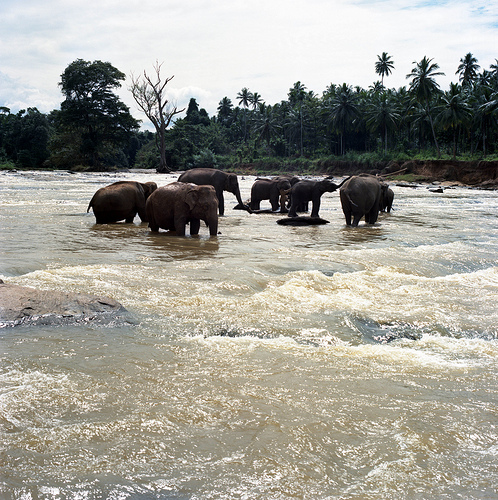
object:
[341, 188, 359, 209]
tail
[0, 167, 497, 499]
river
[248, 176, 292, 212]
animal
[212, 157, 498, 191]
riverbank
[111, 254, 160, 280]
ripples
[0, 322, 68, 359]
ripples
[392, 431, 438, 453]
ripples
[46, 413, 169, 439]
ripples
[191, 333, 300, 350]
ripples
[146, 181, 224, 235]
elephant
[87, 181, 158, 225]
elephant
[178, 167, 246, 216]
elephant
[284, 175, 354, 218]
elephant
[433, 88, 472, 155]
tree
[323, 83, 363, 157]
tree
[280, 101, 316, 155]
tree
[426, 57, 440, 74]
palm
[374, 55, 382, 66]
palm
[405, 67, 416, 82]
palm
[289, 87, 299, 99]
palm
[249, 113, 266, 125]
palm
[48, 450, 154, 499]
ripple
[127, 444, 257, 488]
ripple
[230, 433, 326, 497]
ripple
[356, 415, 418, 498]
ripple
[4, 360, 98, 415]
ripple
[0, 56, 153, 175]
trees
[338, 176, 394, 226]
animal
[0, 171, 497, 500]
water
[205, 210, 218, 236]
elephant trunk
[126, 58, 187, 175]
tree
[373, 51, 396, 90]
tree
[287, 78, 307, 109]
tree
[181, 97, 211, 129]
tree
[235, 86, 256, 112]
tree